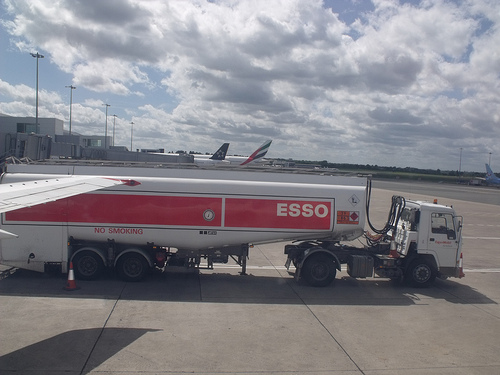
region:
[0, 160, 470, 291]
This is a truck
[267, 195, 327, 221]
This is a company name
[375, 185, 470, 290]
This is a head of a truck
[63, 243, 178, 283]
These are hind wheels of a truck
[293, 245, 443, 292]
These are front wheels of a truck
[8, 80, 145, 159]
These are electric poles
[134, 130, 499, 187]
These are aeroplanes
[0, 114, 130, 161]
These are buildings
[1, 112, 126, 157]
These are white buildings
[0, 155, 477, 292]
This is a white and red truck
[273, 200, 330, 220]
white writing on side of truck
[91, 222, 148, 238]
red warning sign on truck side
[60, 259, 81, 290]
red and white safety cone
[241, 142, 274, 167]
red and blue airplane tail fin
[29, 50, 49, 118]
silver metal runway light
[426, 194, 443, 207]
orange light on truck cab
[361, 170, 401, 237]
black rubber hosing on back of truck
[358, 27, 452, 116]
large clouds in sky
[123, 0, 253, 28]
sun shining through clouds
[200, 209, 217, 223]
design on side of truck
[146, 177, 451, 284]
this is a lorry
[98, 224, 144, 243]
this is a writing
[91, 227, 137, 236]
the writing is in red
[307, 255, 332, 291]
this is a wheel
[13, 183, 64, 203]
this is a wing of the jet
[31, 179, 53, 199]
the wing is white in color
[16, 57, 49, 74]
this is the sky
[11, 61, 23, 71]
the sky is blue in color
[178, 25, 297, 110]
these are the clouds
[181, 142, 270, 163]
this is a jet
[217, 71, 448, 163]
the sky is cloudy and dark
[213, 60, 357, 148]
the sky is cloudy and dark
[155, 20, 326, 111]
the sky is cloudy and dark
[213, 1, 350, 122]
the sky is cloudy and dark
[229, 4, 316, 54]
the sky is cloudy and dark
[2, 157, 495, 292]
A semi pulls a huge load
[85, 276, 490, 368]
Shadow from the tractor trailer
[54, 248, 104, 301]
Orange and white cone on the ground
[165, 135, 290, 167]
Planes parked in the background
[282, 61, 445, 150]
Sky with tons of clouds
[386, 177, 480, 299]
Tractor trailer front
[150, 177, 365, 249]
White and red colored trailer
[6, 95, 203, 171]
Buildings in the background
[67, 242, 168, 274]
Set of wheels on the trailer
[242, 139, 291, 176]
Tail fin on the plane